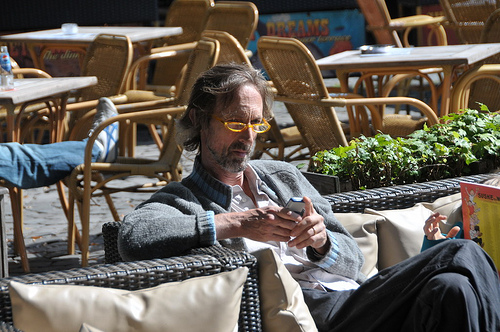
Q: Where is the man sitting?
A: On a bench.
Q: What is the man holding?
A: A cellphone.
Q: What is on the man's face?
A: Eyeglasses.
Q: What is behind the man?
A: Table and chairs.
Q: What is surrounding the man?
A: Pillows.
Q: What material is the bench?
A: Wicker.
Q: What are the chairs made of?
A: Wood.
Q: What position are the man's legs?
A: Crossed.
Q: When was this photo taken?
A: In the daytime.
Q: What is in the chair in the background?
A: Person's foot.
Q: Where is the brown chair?
A: Near a table.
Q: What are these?
A: A row of plants.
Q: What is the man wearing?
A: Grey sweater.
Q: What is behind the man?
A: Grey patio sofa.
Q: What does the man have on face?
A: Sunglasses.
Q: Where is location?
A: Outside patio area.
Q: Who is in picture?
A: People.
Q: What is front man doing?
A: Talking on phone.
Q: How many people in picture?
A: Two.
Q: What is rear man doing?
A: Resting his foot on chair.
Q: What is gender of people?
A: Males.